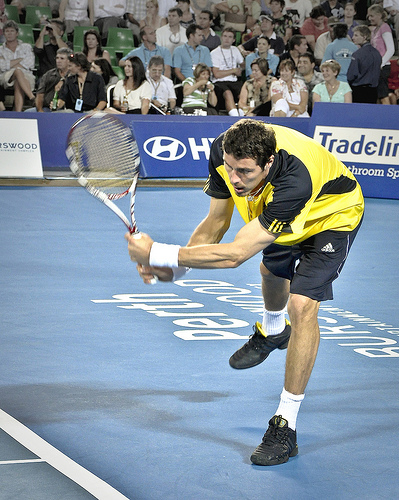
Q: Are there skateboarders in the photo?
A: No, there are no skateboarders.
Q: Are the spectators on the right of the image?
A: Yes, the spectators are on the right of the image.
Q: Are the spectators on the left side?
A: No, the spectators are on the right of the image.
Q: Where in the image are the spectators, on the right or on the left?
A: The spectators are on the right of the image.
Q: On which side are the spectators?
A: The spectators are on the right of the image.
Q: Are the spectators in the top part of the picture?
A: Yes, the spectators are in the top of the image.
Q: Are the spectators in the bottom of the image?
A: No, the spectators are in the top of the image.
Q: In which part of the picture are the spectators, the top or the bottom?
A: The spectators are in the top of the image.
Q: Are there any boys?
A: No, there are no boys.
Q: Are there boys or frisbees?
A: No, there are no boys or frisbees.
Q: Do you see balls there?
A: No, there are no balls.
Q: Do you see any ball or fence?
A: No, there are no balls or fences.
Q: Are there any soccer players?
A: No, there are no soccer players.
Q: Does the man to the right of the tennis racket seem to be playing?
A: Yes, the man is playing.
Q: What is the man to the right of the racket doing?
A: The man is playing.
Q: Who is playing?
A: The man is playing.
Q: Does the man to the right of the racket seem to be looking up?
A: No, the man is playing.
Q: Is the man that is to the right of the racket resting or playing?
A: The man is playing.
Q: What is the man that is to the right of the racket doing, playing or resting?
A: The man is playing.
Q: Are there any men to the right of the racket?
A: Yes, there is a man to the right of the racket.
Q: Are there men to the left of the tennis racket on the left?
A: No, the man is to the right of the tennis racket.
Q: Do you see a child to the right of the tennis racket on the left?
A: No, there is a man to the right of the tennis racket.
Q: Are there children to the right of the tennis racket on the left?
A: No, there is a man to the right of the tennis racket.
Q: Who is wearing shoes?
A: The man is wearing shoes.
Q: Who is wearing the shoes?
A: The man is wearing shoes.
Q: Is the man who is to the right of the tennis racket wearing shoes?
A: Yes, the man is wearing shoes.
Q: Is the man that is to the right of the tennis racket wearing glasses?
A: No, the man is wearing shoes.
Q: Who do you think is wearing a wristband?
A: The man is wearing a wristband.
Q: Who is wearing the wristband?
A: The man is wearing a wristband.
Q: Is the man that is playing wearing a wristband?
A: Yes, the man is wearing a wristband.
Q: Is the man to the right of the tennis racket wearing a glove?
A: No, the man is wearing a wristband.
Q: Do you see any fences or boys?
A: No, there are no boys or fences.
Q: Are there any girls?
A: No, there are no girls.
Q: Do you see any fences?
A: No, there are no fences.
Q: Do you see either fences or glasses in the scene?
A: No, there are no fences or glasses.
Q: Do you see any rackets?
A: Yes, there is a racket.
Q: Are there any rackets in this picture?
A: Yes, there is a racket.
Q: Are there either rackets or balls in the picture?
A: Yes, there is a racket.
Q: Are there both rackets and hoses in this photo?
A: No, there is a racket but no hoses.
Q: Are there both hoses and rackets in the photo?
A: No, there is a racket but no hoses.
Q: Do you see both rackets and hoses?
A: No, there is a racket but no hoses.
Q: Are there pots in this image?
A: No, there are no pots.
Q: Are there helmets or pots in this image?
A: No, there are no pots or helmets.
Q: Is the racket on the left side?
A: Yes, the racket is on the left of the image.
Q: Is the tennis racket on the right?
A: No, the tennis racket is on the left of the image.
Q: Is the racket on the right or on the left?
A: The racket is on the left of the image.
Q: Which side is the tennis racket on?
A: The tennis racket is on the left of the image.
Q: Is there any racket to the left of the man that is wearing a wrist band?
A: Yes, there is a racket to the left of the man.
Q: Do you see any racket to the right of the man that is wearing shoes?
A: No, the racket is to the left of the man.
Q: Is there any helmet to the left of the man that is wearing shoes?
A: No, there is a racket to the left of the man.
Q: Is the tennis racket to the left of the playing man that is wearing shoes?
A: Yes, the tennis racket is to the left of the man.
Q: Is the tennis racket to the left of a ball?
A: No, the tennis racket is to the left of the man.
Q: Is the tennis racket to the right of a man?
A: No, the tennis racket is to the left of a man.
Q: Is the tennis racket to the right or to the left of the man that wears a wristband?
A: The tennis racket is to the left of the man.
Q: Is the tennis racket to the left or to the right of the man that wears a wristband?
A: The tennis racket is to the left of the man.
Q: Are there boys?
A: No, there are no boys.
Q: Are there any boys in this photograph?
A: No, there are no boys.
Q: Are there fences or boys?
A: No, there are no boys or fences.